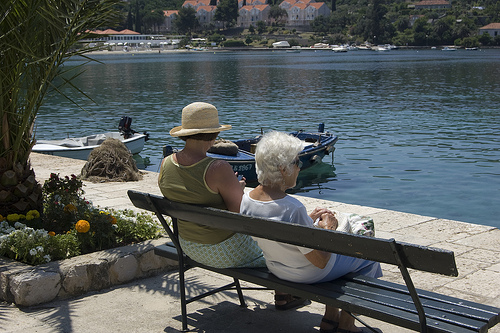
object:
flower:
[30, 248, 36, 256]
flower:
[43, 254, 51, 263]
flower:
[75, 219, 91, 233]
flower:
[26, 210, 41, 220]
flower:
[6, 213, 20, 222]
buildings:
[158, 0, 327, 30]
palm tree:
[2, 0, 111, 215]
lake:
[15, 49, 500, 227]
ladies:
[236, 129, 384, 333]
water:
[31, 46, 500, 226]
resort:
[71, 28, 142, 41]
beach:
[80, 46, 207, 52]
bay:
[18, 47, 498, 226]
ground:
[412, 136, 430, 170]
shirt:
[241, 191, 337, 283]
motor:
[117, 115, 139, 140]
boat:
[30, 115, 150, 162]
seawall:
[27, 150, 500, 281]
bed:
[0, 173, 185, 307]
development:
[142, 0, 333, 37]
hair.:
[255, 131, 304, 187]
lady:
[154, 101, 309, 310]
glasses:
[285, 160, 299, 167]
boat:
[162, 121, 338, 181]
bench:
[125, 189, 500, 333]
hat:
[169, 101, 231, 139]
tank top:
[158, 151, 239, 244]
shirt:
[158, 152, 232, 244]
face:
[286, 157, 301, 188]